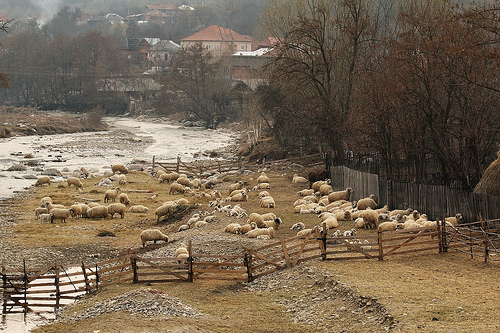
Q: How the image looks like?
A: Field good.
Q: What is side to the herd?
A: Water.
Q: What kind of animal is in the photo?
A: Sheep.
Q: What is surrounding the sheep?
A: A fence.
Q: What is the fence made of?
A: Wood.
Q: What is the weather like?
A: Cloudy and foggy.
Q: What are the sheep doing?
A: Eating.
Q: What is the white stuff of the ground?
A: Snow.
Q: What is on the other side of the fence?
A: Trees.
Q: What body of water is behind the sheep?
A: A small river.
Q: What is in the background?
A: Houses.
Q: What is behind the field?
A: Running water.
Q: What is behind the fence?
A: Houses.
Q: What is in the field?
A: Grazing sheep.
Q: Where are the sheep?
A: Behind the fence.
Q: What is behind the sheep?
A: Running water.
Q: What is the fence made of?
A: Wood.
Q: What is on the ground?
A: Dead grass.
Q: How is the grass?
A: Dead.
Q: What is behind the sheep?
A: Stream of water.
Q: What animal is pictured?
A: Sheep.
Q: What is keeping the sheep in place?
A: Fence.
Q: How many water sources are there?
A: 1.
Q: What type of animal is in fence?
A: Sheep.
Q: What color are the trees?
A: Brown.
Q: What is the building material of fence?
A: Wood.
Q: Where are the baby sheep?
A: With adult sheep.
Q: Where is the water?
A: Beside sheep.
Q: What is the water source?
A: River.